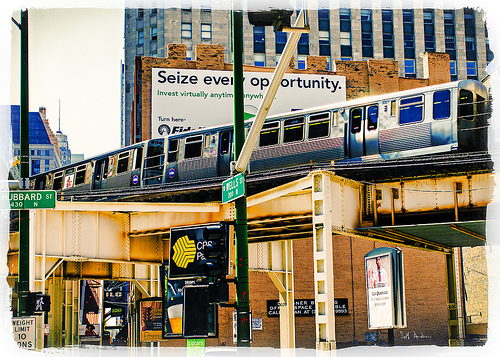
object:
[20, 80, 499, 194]
train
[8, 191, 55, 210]
street signs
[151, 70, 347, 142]
large sign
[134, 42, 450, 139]
building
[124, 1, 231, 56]
offices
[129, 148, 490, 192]
tracks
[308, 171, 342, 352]
support beams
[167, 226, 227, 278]
sign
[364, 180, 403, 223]
large beams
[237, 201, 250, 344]
green post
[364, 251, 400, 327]
advertisment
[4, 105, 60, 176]
buildings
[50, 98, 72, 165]
building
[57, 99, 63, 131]
pole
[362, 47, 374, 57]
windows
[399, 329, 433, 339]
writting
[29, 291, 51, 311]
cross walk sign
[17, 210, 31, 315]
pole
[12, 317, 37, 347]
weight limit sign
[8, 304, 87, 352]
corner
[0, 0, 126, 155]
gray sky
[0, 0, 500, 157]
back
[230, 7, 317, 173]
silver pole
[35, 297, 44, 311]
man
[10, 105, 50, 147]
roof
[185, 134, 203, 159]
windows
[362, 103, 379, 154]
doors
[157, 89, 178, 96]
green words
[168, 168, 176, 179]
blue circle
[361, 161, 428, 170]
steel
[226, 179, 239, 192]
wells st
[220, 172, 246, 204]
sign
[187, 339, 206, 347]
green sign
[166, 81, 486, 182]
cars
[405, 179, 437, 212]
beems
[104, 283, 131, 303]
ads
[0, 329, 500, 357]
street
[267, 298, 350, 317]
black sign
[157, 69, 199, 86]
black letters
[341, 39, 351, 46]
curtians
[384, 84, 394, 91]
bricks